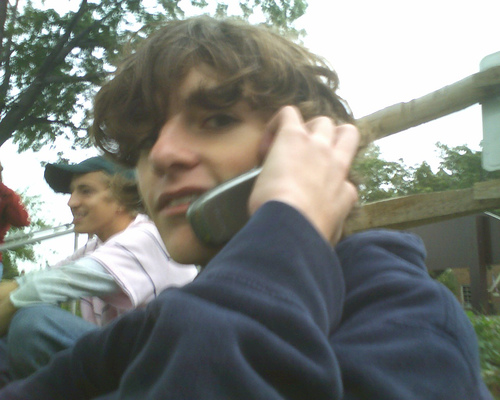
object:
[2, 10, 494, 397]
boy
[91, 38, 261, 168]
bangs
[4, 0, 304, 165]
tree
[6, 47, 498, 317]
fence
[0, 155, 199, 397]
boy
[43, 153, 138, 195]
cap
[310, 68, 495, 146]
wood fence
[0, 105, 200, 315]
arm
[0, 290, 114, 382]
jeans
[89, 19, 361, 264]
head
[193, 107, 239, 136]
eyes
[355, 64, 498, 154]
post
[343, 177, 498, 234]
post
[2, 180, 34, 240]
arm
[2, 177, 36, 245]
red sleeve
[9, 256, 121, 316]
sleeve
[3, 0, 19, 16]
green leaves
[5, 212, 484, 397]
sweatshirt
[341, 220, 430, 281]
hood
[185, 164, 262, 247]
mobile phone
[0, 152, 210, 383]
shirt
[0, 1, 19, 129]
branches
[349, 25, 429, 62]
light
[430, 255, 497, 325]
house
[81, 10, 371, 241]
hair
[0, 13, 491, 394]
jumper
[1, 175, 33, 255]
clothing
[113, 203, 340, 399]
sleeve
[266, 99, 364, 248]
hand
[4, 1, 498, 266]
sky